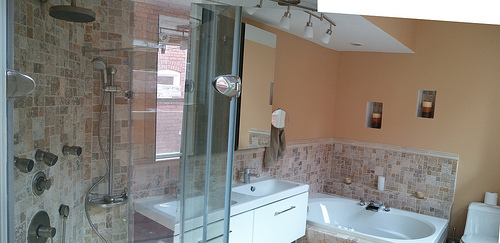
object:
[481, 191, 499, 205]
toilet paper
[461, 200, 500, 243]
toilet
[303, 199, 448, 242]
bath tub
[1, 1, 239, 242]
shower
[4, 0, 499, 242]
bathroom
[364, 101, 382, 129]
hole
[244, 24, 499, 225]
wall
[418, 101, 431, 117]
candle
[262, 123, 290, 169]
towel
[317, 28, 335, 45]
lights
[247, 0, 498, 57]
ceiling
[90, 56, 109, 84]
shower head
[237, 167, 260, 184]
faucet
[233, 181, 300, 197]
sink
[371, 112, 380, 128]
candle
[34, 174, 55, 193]
knob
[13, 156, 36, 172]
knob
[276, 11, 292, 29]
light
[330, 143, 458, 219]
tiles